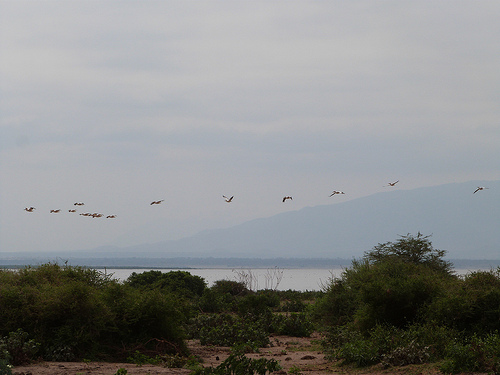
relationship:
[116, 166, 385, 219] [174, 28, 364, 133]
birds in sky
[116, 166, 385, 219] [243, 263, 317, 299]
birds flying over water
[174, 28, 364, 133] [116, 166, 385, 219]
sky above birds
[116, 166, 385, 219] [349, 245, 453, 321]
birds above bush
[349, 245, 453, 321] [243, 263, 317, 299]
bush near water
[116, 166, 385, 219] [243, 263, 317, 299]
birds above water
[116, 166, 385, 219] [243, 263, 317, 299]
birds near water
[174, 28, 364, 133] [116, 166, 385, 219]
sky holds birds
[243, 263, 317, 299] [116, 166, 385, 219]
water below birds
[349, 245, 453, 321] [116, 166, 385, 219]
bush below birds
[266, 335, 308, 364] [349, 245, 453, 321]
sand near bush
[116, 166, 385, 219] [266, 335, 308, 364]
birds above sand